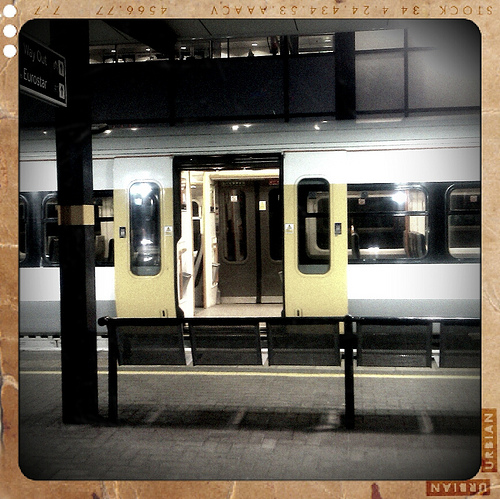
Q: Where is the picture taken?
A: Subway station.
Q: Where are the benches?
A: The platform.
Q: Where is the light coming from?
A: Overhead.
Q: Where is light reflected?
A: The windows.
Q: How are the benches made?
A: Of steel.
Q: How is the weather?
A: Clear.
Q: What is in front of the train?
A: A black metal pole.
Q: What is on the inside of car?
A: White wall and handles.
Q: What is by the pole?
A: A railing with sits.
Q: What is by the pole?
A: A green sign.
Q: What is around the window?
A: A seal to hold it in.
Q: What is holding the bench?
A: Black polls.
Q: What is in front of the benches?
A: A subway car.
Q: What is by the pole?
A: Shadow under the bench.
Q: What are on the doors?
A: Windows and seals.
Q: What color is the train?
A: Silver.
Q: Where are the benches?
A: In front of the train.